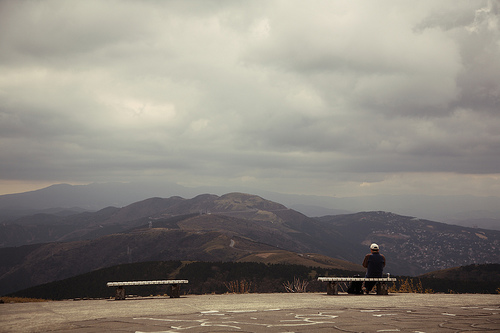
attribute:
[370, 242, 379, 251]
hat — white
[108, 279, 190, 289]
bench — white, here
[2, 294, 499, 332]
floor — stone, decorative, bare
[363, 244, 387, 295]
man — sitting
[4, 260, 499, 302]
hill — forested, here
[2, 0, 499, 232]
sky — grey, cloudy, gloomy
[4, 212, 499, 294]
hill — here, ivsible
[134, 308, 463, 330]
drawing — white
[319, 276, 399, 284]
bench — white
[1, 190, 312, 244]
hill — here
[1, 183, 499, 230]
hill — distnat, here